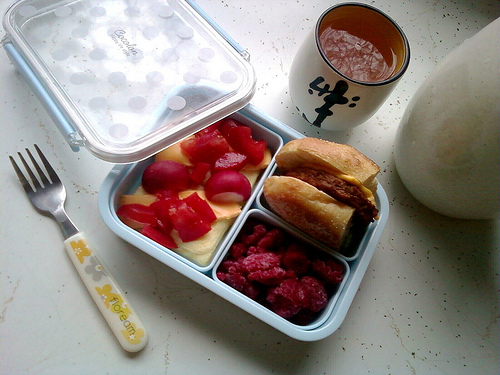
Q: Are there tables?
A: Yes, there is a table.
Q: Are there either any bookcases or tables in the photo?
A: Yes, there is a table.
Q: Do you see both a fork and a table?
A: Yes, there are both a table and a fork.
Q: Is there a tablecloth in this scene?
A: No, there are no tablecloths.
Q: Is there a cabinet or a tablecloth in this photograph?
A: No, there are no tablecloths or cabinets.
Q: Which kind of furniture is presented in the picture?
A: The furniture is a table.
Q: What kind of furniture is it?
A: The piece of furniture is a table.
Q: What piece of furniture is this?
A: This is a table.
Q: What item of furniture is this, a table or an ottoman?
A: This is a table.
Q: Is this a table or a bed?
A: This is a table.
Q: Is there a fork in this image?
A: Yes, there is a fork.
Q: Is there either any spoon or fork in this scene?
A: Yes, there is a fork.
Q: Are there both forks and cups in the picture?
A: Yes, there are both a fork and a cup.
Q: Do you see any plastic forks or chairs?
A: Yes, there is a plastic fork.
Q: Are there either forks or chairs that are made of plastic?
A: Yes, the fork is made of plastic.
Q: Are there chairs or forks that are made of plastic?
A: Yes, the fork is made of plastic.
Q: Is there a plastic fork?
A: Yes, there is a fork that is made of plastic.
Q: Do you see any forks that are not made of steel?
A: Yes, there is a fork that is made of plastic.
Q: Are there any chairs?
A: No, there are no chairs.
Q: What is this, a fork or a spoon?
A: This is a fork.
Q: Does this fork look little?
A: Yes, the fork is little.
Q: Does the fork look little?
A: Yes, the fork is little.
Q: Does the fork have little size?
A: Yes, the fork is little.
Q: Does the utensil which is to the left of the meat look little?
A: Yes, the fork is little.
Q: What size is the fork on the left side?
A: The fork is little.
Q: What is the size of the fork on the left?
A: The fork is little.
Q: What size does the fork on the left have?
A: The fork has little size.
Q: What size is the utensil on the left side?
A: The fork is little.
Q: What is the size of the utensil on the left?
A: The fork is little.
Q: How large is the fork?
A: The fork is little.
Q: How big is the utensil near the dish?
A: The fork is little.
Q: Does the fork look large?
A: No, the fork is little.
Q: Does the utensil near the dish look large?
A: No, the fork is little.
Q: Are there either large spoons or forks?
A: No, there is a fork but it is little.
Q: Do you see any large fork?
A: No, there is a fork but it is little.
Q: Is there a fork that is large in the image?
A: No, there is a fork but it is little.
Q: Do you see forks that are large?
A: No, there is a fork but it is little.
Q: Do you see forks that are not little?
A: No, there is a fork but it is little.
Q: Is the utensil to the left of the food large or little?
A: The fork is little.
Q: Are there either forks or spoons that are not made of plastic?
A: No, there is a fork but it is made of plastic.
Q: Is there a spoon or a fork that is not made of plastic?
A: No, there is a fork but it is made of plastic.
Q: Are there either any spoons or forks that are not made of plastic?
A: No, there is a fork but it is made of plastic.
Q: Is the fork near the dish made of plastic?
A: Yes, the fork is made of plastic.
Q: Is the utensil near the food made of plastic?
A: Yes, the fork is made of plastic.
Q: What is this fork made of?
A: The fork is made of plastic.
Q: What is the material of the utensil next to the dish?
A: The fork is made of plastic.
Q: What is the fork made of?
A: The fork is made of plastic.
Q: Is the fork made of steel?
A: No, the fork is made of plastic.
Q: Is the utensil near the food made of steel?
A: No, the fork is made of plastic.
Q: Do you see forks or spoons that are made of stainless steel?
A: No, there is a fork but it is made of plastic.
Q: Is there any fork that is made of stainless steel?
A: No, there is a fork but it is made of plastic.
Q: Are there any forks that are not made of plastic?
A: No, there is a fork but it is made of plastic.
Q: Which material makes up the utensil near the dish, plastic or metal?
A: The fork is made of plastic.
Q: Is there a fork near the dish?
A: Yes, there is a fork near the dish.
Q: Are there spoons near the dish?
A: No, there is a fork near the dish.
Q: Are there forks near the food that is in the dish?
A: Yes, there is a fork near the food.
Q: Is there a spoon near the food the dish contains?
A: No, there is a fork near the food.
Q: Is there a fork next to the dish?
A: Yes, there is a fork next to the dish.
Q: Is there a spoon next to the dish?
A: No, there is a fork next to the dish.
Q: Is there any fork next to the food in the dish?
A: Yes, there is a fork next to the food.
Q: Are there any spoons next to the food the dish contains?
A: No, there is a fork next to the food.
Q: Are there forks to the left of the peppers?
A: Yes, there is a fork to the left of the peppers.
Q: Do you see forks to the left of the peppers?
A: Yes, there is a fork to the left of the peppers.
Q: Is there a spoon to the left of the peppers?
A: No, there is a fork to the left of the peppers.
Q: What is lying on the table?
A: The fork is lying on the table.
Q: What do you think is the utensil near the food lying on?
A: The fork is lying on the table.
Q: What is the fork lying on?
A: The fork is lying on the table.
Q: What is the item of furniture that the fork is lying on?
A: The piece of furniture is a table.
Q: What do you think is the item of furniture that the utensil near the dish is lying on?
A: The piece of furniture is a table.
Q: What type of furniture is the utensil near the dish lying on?
A: The fork is lying on the table.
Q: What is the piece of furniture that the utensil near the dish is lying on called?
A: The piece of furniture is a table.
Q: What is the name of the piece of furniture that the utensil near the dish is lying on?
A: The piece of furniture is a table.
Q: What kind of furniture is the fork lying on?
A: The fork is lying on the table.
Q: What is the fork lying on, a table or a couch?
A: The fork is lying on a table.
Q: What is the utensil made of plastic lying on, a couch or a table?
A: The fork is lying on a table.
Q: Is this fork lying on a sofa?
A: No, the fork is lying on the table.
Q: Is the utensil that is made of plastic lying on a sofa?
A: No, the fork is lying on the table.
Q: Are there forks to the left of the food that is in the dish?
A: Yes, there is a fork to the left of the food.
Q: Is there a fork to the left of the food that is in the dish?
A: Yes, there is a fork to the left of the food.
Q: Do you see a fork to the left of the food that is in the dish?
A: Yes, there is a fork to the left of the food.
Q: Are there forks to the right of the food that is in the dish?
A: No, the fork is to the left of the food.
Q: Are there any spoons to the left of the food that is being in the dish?
A: No, there is a fork to the left of the food.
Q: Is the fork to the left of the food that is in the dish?
A: Yes, the fork is to the left of the food.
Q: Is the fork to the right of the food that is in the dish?
A: No, the fork is to the left of the food.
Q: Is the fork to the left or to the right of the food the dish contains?
A: The fork is to the left of the food.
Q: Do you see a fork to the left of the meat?
A: Yes, there is a fork to the left of the meat.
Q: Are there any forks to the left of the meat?
A: Yes, there is a fork to the left of the meat.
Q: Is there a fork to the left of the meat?
A: Yes, there is a fork to the left of the meat.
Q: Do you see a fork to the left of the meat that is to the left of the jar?
A: Yes, there is a fork to the left of the meat.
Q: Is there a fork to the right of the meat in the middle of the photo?
A: No, the fork is to the left of the meat.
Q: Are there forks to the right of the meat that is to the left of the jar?
A: No, the fork is to the left of the meat.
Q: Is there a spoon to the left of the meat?
A: No, there is a fork to the left of the meat.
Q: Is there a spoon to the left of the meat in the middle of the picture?
A: No, there is a fork to the left of the meat.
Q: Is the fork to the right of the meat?
A: No, the fork is to the left of the meat.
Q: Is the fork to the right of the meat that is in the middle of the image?
A: No, the fork is to the left of the meat.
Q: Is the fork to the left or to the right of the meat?
A: The fork is to the left of the meat.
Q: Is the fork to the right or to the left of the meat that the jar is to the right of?
A: The fork is to the left of the meat.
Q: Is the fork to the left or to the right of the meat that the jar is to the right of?
A: The fork is to the left of the meat.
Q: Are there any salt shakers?
A: No, there are no salt shakers.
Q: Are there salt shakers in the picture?
A: No, there are no salt shakers.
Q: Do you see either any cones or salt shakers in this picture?
A: No, there are no salt shakers or cones.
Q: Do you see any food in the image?
A: Yes, there is food.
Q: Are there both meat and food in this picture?
A: Yes, there are both food and meat.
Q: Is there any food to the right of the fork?
A: Yes, there is food to the right of the fork.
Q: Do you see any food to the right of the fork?
A: Yes, there is food to the right of the fork.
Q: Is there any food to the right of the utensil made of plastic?
A: Yes, there is food to the right of the fork.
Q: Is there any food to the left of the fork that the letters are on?
A: No, the food is to the right of the fork.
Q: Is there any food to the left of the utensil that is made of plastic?
A: No, the food is to the right of the fork.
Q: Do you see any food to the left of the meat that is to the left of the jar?
A: Yes, there is food to the left of the meat.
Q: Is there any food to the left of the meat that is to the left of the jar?
A: Yes, there is food to the left of the meat.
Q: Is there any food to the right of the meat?
A: No, the food is to the left of the meat.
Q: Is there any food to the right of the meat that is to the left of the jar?
A: No, the food is to the left of the meat.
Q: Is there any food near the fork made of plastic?
A: Yes, there is food near the fork.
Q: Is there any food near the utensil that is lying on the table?
A: Yes, there is food near the fork.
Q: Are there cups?
A: Yes, there is a cup.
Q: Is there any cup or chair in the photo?
A: Yes, there is a cup.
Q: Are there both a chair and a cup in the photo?
A: No, there is a cup but no chairs.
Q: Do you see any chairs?
A: No, there are no chairs.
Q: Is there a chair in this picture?
A: No, there are no chairs.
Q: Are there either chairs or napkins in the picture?
A: No, there are no chairs or napkins.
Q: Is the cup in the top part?
A: Yes, the cup is in the top of the image.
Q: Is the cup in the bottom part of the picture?
A: No, the cup is in the top of the image.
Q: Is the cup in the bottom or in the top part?
A: The cup is in the top of the image.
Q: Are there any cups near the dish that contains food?
A: Yes, there is a cup near the dish.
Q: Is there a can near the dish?
A: No, there is a cup near the dish.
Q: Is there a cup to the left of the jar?
A: Yes, there is a cup to the left of the jar.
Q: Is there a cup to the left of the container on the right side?
A: Yes, there is a cup to the left of the jar.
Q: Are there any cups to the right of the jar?
A: No, the cup is to the left of the jar.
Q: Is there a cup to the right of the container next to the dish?
A: No, the cup is to the left of the jar.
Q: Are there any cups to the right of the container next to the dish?
A: No, the cup is to the left of the jar.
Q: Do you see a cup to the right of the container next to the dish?
A: No, the cup is to the left of the jar.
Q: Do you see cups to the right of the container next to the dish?
A: No, the cup is to the left of the jar.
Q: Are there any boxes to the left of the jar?
A: No, there is a cup to the left of the jar.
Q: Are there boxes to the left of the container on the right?
A: No, there is a cup to the left of the jar.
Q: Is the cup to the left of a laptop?
A: No, the cup is to the left of the jar.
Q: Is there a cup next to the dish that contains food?
A: Yes, there is a cup next to the dish.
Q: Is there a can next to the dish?
A: No, there is a cup next to the dish.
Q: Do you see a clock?
A: No, there are no clocks.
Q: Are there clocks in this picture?
A: No, there are no clocks.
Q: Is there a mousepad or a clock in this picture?
A: No, there are no clocks or mouse pads.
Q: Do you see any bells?
A: No, there are no bells.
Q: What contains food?
A: The dish contains food.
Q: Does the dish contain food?
A: Yes, the dish contains food.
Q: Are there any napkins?
A: No, there are no napkins.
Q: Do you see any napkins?
A: No, there are no napkins.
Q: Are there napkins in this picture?
A: No, there are no napkins.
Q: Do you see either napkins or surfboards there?
A: No, there are no napkins or surfboards.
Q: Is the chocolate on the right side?
A: Yes, the chocolate is on the right of the image.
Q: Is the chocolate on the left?
A: No, the chocolate is on the right of the image.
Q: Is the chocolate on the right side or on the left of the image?
A: The chocolate is on the right of the image.